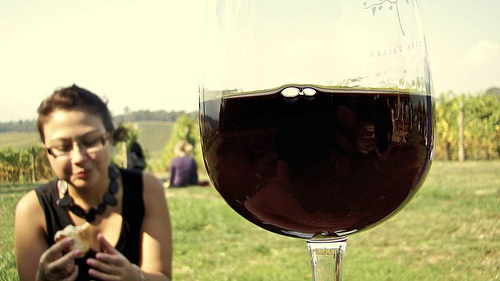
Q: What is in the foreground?
A: A glass of wine.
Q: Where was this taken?
A: At a park.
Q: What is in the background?
A: Trees.